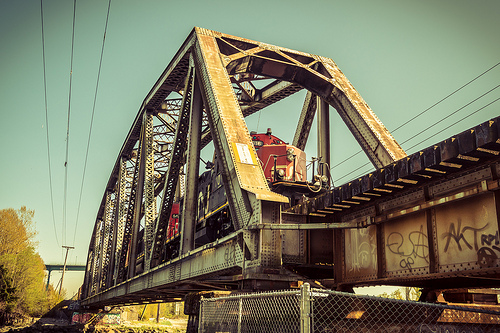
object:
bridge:
[72, 209, 337, 332]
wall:
[194, 27, 271, 189]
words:
[384, 224, 432, 271]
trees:
[0, 203, 47, 327]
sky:
[0, 0, 499, 300]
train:
[125, 127, 309, 274]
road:
[33, 317, 61, 324]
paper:
[234, 141, 254, 164]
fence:
[198, 285, 308, 332]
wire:
[71, 0, 114, 248]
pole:
[57, 248, 71, 295]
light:
[274, 167, 287, 179]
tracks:
[286, 114, 500, 214]